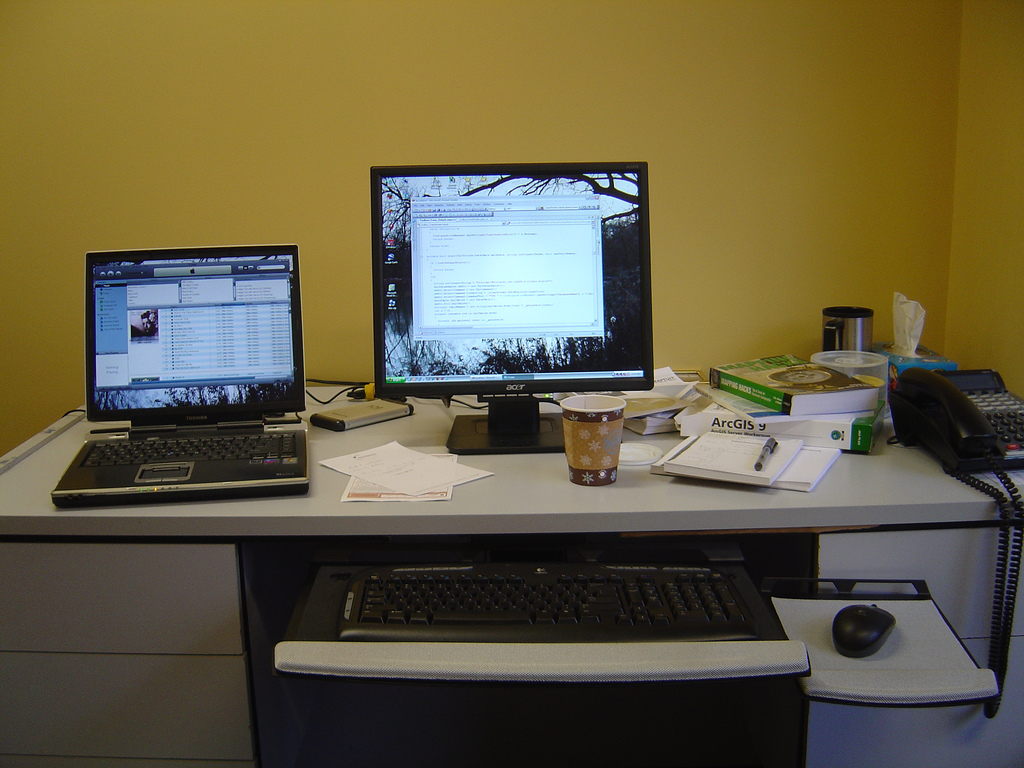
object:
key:
[532, 611, 556, 625]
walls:
[0, 0, 1024, 457]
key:
[578, 612, 602, 623]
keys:
[358, 574, 407, 624]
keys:
[384, 562, 442, 623]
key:
[406, 591, 422, 602]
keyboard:
[336, 562, 760, 644]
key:
[532, 599, 549, 611]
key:
[558, 573, 575, 585]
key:
[588, 585, 621, 597]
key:
[458, 591, 474, 602]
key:
[436, 605, 452, 611]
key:
[722, 603, 746, 621]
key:
[607, 574, 624, 583]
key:
[515, 599, 532, 608]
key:
[430, 608, 532, 626]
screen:
[369, 162, 656, 399]